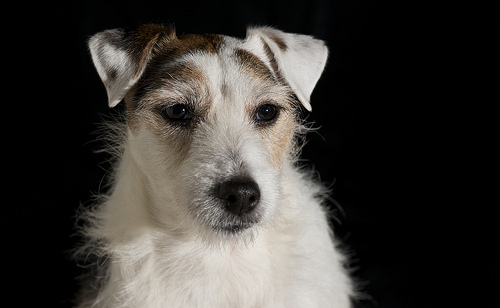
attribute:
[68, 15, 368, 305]
dog — white, brown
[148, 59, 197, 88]
marks — brown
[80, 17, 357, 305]
spotted dog — white and brown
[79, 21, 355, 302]
dog — white, brown, spotted           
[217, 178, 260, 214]
nose — black      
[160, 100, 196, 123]
eye — black      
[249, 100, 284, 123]
eye — black           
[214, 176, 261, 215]
black nose — on a Jack Russel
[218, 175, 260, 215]
black nose — on a Jack Russel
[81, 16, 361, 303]
white/brown dog — spotted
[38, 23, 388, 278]
dog — white, brown, spotted